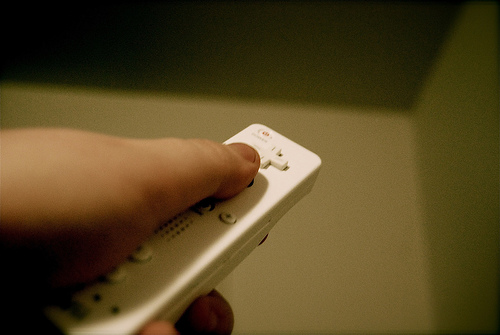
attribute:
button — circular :
[127, 242, 154, 263]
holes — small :
[144, 206, 199, 240]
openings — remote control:
[155, 211, 200, 238]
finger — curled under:
[180, 286, 235, 334]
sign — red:
[254, 125, 274, 140]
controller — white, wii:
[41, 119, 323, 334]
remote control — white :
[45, 111, 348, 333]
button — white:
[129, 240, 156, 261]